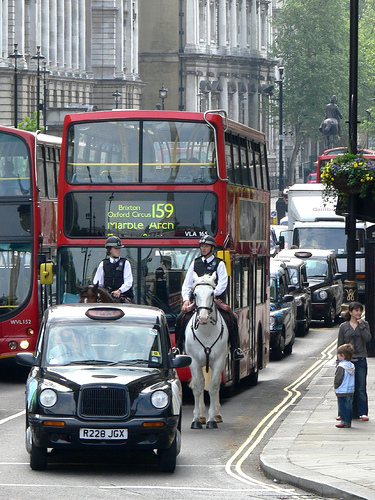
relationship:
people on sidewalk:
[336, 298, 367, 377] [298, 383, 339, 438]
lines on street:
[222, 432, 257, 484] [0, 388, 264, 498]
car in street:
[15, 303, 193, 471] [42, 469, 237, 498]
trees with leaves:
[257, 2, 374, 186] [257, 3, 373, 154]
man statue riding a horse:
[307, 75, 347, 131] [306, 72, 354, 165]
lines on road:
[227, 340, 336, 461] [12, 385, 266, 498]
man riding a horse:
[172, 234, 246, 359] [183, 270, 229, 429]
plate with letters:
[80, 426, 128, 441] [82, 428, 124, 437]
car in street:
[15, 253, 207, 494] [0, 391, 297, 499]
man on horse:
[172, 234, 246, 359] [175, 218, 265, 430]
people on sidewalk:
[336, 300, 371, 422] [259, 353, 374, 498]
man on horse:
[172, 233, 248, 361] [183, 270, 229, 429]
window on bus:
[81, 114, 240, 330] [35, 72, 283, 348]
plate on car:
[76, 426, 133, 443] [25, 278, 180, 479]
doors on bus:
[245, 258, 259, 373] [56, 108, 273, 399]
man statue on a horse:
[323, 93, 344, 137] [304, 111, 359, 162]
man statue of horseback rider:
[323, 93, 344, 137] [323, 91, 344, 116]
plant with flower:
[317, 152, 373, 212] [351, 161, 357, 169]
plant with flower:
[317, 152, 373, 212] [357, 158, 364, 166]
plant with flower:
[317, 152, 373, 212] [329, 175, 335, 183]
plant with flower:
[317, 152, 373, 212] [364, 173, 371, 181]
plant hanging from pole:
[317, 152, 373, 212] [345, 1, 361, 292]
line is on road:
[222, 311, 372, 499] [3, 218, 371, 499]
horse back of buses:
[185, 231, 232, 418] [3, 102, 274, 399]